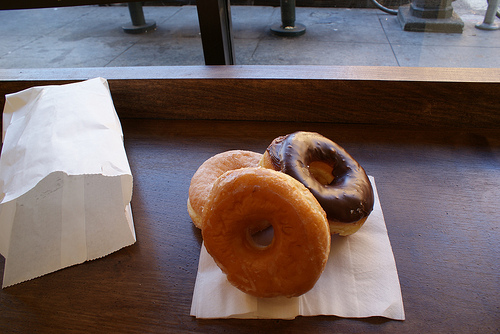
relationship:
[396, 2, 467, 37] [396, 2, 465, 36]
piller has base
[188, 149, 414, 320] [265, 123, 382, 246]
napkin under donut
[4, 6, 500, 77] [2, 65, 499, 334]
window next to counter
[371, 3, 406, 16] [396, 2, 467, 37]
bicycle near pillar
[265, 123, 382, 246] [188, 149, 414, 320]
donut on napkin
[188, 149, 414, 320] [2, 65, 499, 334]
napkin on counter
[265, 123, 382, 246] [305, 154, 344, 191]
donut has whole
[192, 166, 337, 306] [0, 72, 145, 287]
donut near bag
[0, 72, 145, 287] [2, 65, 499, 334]
bag on counter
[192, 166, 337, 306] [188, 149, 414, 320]
donut on napkin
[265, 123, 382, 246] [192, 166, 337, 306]
donut near donut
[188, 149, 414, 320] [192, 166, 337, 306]
napkin under donut